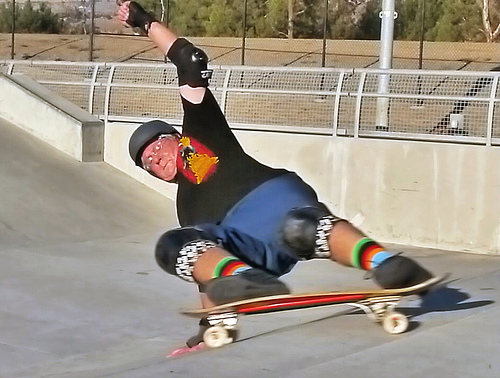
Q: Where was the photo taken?
A: It was taken at the park.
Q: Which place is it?
A: It is a park.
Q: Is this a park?
A: Yes, it is a park.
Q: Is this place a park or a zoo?
A: It is a park.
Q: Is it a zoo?
A: No, it is a park.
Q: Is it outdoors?
A: Yes, it is outdoors.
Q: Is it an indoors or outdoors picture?
A: It is outdoors.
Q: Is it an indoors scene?
A: No, it is outdoors.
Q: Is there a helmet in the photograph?
A: Yes, there is a helmet.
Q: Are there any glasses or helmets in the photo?
A: Yes, there is a helmet.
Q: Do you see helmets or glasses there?
A: Yes, there is a helmet.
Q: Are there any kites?
A: No, there are no kites.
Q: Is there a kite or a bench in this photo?
A: No, there are no kites or benches.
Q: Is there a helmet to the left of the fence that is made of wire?
A: Yes, there is a helmet to the left of the fence.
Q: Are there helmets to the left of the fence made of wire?
A: Yes, there is a helmet to the left of the fence.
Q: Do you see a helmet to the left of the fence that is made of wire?
A: Yes, there is a helmet to the left of the fence.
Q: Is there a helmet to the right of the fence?
A: No, the helmet is to the left of the fence.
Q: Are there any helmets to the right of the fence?
A: No, the helmet is to the left of the fence.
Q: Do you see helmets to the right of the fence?
A: No, the helmet is to the left of the fence.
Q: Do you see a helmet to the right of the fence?
A: No, the helmet is to the left of the fence.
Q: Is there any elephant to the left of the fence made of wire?
A: No, there is a helmet to the left of the fence.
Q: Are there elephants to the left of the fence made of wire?
A: No, there is a helmet to the left of the fence.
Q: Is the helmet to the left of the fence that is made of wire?
A: Yes, the helmet is to the left of the fence.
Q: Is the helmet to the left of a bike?
A: No, the helmet is to the left of the fence.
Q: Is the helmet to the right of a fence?
A: No, the helmet is to the left of a fence.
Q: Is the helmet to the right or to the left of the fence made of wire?
A: The helmet is to the left of the fence.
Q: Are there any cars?
A: No, there are no cars.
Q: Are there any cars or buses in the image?
A: No, there are no cars or buses.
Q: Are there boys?
A: No, there are no boys.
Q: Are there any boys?
A: No, there are no boys.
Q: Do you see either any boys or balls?
A: No, there are no boys or balls.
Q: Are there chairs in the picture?
A: No, there are no chairs.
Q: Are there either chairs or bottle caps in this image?
A: No, there are no chairs or bottle caps.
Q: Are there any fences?
A: Yes, there is a fence.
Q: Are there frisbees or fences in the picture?
A: Yes, there is a fence.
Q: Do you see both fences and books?
A: No, there is a fence but no books.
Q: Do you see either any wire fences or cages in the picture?
A: Yes, there is a wire fence.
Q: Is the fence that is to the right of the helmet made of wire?
A: Yes, the fence is made of wire.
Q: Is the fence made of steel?
A: No, the fence is made of wire.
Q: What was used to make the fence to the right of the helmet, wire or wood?
A: The fence is made of wire.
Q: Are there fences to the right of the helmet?
A: Yes, there is a fence to the right of the helmet.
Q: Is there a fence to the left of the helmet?
A: No, the fence is to the right of the helmet.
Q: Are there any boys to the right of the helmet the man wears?
A: No, there is a fence to the right of the helmet.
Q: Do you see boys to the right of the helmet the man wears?
A: No, there is a fence to the right of the helmet.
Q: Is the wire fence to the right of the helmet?
A: Yes, the fence is to the right of the helmet.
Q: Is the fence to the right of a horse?
A: No, the fence is to the right of the helmet.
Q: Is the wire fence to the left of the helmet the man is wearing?
A: No, the fence is to the right of the helmet.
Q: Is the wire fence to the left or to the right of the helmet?
A: The fence is to the right of the helmet.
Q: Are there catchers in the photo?
A: No, there are no catchers.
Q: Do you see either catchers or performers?
A: No, there are no catchers or performers.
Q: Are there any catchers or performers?
A: No, there are no catchers or performers.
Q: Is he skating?
A: Yes, the man is skating.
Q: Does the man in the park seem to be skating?
A: Yes, the man is skating.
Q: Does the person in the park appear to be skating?
A: Yes, the man is skating.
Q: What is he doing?
A: The man is skating.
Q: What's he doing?
A: The man is skating.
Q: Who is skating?
A: The man is skating.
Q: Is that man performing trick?
A: No, the man is skating.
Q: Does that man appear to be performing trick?
A: No, the man is skating.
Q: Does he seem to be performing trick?
A: No, the man is skating.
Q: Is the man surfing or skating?
A: The man is skating.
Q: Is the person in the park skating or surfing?
A: The man is skating.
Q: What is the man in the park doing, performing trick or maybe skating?
A: The man is skating.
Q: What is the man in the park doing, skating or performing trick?
A: The man is skating.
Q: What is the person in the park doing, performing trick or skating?
A: The man is skating.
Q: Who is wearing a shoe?
A: The man is wearing a shoe.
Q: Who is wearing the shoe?
A: The man is wearing a shoe.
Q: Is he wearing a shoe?
A: Yes, the man is wearing a shoe.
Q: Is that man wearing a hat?
A: No, the man is wearing a shoe.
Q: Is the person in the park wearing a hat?
A: No, the man is wearing a shoe.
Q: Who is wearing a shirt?
A: The man is wearing a shirt.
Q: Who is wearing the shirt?
A: The man is wearing a shirt.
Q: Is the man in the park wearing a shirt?
A: Yes, the man is wearing a shirt.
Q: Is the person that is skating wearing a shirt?
A: Yes, the man is wearing a shirt.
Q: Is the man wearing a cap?
A: No, the man is wearing a shirt.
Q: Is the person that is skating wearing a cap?
A: No, the man is wearing a shirt.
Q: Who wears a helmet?
A: The man wears a helmet.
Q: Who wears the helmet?
A: The man wears a helmet.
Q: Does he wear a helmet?
A: Yes, the man wears a helmet.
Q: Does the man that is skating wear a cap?
A: No, the man wears a helmet.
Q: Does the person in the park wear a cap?
A: No, the man wears a helmet.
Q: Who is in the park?
A: The man is in the park.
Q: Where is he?
A: The man is in the park.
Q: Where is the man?
A: The man is in the park.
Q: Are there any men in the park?
A: Yes, there is a man in the park.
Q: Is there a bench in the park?
A: No, there is a man in the park.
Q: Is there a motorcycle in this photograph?
A: No, there are no motorcycles.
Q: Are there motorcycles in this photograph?
A: No, there are no motorcycles.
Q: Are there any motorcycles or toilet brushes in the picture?
A: No, there are no motorcycles or toilet brushes.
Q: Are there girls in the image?
A: No, there are no girls.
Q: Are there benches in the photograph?
A: No, there are no benches.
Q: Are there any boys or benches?
A: No, there are no benches or boys.